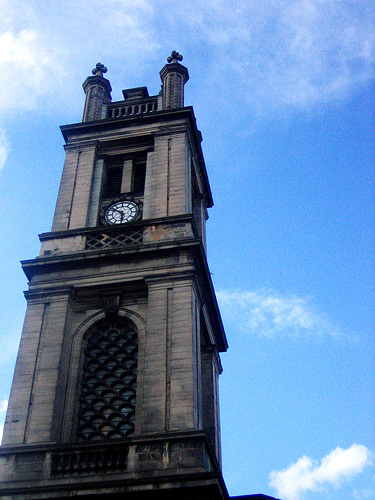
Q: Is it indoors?
A: Yes, it is indoors.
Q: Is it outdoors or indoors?
A: It is indoors.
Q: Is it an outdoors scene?
A: No, it is indoors.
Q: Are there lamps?
A: No, there are no lamps.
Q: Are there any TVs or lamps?
A: No, there are no lamps or tvs.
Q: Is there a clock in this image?
A: Yes, there is a clock.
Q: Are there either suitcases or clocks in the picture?
A: Yes, there is a clock.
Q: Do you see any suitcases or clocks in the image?
A: Yes, there is a clock.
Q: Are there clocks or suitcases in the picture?
A: Yes, there is a clock.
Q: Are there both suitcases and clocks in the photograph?
A: No, there is a clock but no suitcases.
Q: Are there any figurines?
A: No, there are no figurines.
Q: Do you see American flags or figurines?
A: No, there are no figurines or American flags.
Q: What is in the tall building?
A: The clock is in the clock tower.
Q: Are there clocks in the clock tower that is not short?
A: Yes, there is a clock in the clock tower.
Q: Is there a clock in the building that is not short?
A: Yes, there is a clock in the clock tower.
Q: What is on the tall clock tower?
A: The clock is on the clock tower.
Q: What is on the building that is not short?
A: The clock is on the clock tower.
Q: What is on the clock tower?
A: The clock is on the clock tower.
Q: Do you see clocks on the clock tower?
A: Yes, there is a clock on the clock tower.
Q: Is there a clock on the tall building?
A: Yes, there is a clock on the clock tower.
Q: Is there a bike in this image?
A: No, there are no bikes.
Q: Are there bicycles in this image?
A: No, there are no bicycles.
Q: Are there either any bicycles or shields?
A: No, there are no bicycles or shields.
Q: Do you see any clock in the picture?
A: Yes, there is a clock.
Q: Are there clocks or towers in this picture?
A: Yes, there is a clock.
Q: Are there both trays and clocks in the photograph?
A: No, there is a clock but no trays.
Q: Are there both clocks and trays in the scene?
A: No, there is a clock but no trays.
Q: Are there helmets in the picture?
A: No, there are no helmets.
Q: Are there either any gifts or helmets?
A: No, there are no helmets or gifts.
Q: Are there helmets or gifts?
A: No, there are no helmets or gifts.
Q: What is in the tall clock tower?
A: The clock is in the clock tower.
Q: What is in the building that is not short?
A: The clock is in the clock tower.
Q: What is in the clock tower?
A: The clock is in the clock tower.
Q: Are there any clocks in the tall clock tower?
A: Yes, there is a clock in the clock tower.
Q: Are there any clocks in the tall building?
A: Yes, there is a clock in the clock tower.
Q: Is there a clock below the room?
A: Yes, there is a clock below the room.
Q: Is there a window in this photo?
A: Yes, there is a window.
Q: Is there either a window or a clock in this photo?
A: Yes, there is a window.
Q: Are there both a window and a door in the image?
A: No, there is a window but no doors.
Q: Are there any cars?
A: No, there are no cars.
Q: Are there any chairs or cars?
A: No, there are no cars or chairs.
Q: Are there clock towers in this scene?
A: Yes, there is a clock tower.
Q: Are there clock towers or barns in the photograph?
A: Yes, there is a clock tower.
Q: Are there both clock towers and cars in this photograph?
A: No, there is a clock tower but no cars.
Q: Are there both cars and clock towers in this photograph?
A: No, there is a clock tower but no cars.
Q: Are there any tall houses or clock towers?
A: Yes, there is a tall clock tower.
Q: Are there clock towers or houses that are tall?
A: Yes, the clock tower is tall.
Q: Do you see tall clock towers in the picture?
A: Yes, there is a tall clock tower.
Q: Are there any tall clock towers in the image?
A: Yes, there is a tall clock tower.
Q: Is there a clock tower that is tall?
A: Yes, there is a clock tower that is tall.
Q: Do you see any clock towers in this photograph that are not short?
A: Yes, there is a tall clock tower.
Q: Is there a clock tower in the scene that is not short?
A: Yes, there is a tall clock tower.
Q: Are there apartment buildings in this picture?
A: No, there are no apartment buildings.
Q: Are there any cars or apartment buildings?
A: No, there are no apartment buildings or cars.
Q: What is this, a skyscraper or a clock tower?
A: This is a clock tower.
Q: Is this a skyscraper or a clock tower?
A: This is a clock tower.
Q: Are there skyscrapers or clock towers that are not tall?
A: No, there is a clock tower but it is tall.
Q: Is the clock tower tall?
A: Yes, the clock tower is tall.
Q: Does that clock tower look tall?
A: Yes, the clock tower is tall.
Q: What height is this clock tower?
A: The clock tower is tall.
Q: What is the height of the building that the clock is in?
A: The clock tower is tall.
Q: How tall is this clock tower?
A: The clock tower is tall.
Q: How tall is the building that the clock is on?
A: The clock tower is tall.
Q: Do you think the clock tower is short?
A: No, the clock tower is tall.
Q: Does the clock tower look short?
A: No, the clock tower is tall.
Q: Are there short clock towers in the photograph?
A: No, there is a clock tower but it is tall.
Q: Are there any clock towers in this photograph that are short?
A: No, there is a clock tower but it is tall.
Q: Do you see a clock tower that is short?
A: No, there is a clock tower but it is tall.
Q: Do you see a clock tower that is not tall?
A: No, there is a clock tower but it is tall.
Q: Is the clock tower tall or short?
A: The clock tower is tall.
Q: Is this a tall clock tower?
A: Yes, this is a tall clock tower.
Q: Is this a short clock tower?
A: No, this is a tall clock tower.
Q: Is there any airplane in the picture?
A: No, there are no airplanes.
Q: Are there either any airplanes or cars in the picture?
A: No, there are no airplanes or cars.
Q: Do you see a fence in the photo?
A: Yes, there is a fence.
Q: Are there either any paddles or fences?
A: Yes, there is a fence.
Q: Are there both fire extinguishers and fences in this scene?
A: No, there is a fence but no fire extinguishers.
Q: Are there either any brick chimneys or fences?
A: Yes, there is a brick fence.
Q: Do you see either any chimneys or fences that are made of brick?
A: Yes, the fence is made of brick.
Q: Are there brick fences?
A: Yes, there is a fence that is made of brick.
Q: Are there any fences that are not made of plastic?
A: Yes, there is a fence that is made of brick.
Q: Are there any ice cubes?
A: No, there are no ice cubes.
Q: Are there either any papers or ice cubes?
A: No, there are no ice cubes or papers.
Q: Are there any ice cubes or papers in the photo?
A: No, there are no ice cubes or papers.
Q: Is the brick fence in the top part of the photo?
A: Yes, the fence is in the top of the image.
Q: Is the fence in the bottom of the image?
A: No, the fence is in the top of the image.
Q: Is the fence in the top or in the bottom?
A: The fence is in the top of the image.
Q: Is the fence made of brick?
A: Yes, the fence is made of brick.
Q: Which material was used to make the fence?
A: The fence is made of brick.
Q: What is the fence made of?
A: The fence is made of brick.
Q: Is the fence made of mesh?
A: No, the fence is made of brick.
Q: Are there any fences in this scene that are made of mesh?
A: No, there is a fence but it is made of brick.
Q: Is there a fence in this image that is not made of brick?
A: No, there is a fence but it is made of brick.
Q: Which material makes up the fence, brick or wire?
A: The fence is made of brick.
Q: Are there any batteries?
A: No, there are no batteries.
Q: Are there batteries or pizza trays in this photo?
A: No, there are no batteries or pizza trays.